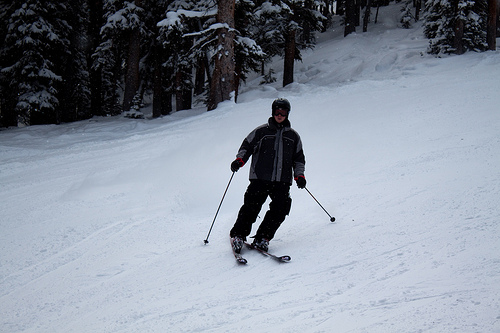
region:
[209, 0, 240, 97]
a large tree trunk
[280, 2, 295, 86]
a large tree trunk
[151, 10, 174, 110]
a large tree trunk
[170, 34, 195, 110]
a large tree trunk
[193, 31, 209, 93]
a large tree trunk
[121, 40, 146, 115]
a large tree trunk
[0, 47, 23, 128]
a large tree trunk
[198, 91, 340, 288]
a person skating on ice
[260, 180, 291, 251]
a person's leg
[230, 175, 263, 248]
a person's leg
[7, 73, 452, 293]
Snow is covering the ground.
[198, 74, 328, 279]
The person is wearing a snow suit.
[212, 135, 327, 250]
The person has poles in their hands.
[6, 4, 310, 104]
Pine trees in the background.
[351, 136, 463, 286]
The snow is white.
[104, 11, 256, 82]
Snow is covering the trees.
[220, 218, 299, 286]
Skis on the person's feet.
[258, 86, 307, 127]
Googles on the person's head.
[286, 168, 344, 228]
The poles are black.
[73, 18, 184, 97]
The leaves are green.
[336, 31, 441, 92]
a few piles of snow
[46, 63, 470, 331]
a snow covered slope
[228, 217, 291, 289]
a pair of skis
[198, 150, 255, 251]
a black ski pole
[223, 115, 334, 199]
a grey and blue jacket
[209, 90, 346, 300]
a young person skiing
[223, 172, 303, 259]
a pair of black snow pants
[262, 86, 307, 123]
a hard black helmet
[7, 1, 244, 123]
a few snow covered trees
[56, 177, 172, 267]
ski tracks in the snow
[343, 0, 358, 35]
a large tree trunk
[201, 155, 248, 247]
a skating stick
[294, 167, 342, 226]
a skating stick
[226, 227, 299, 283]
skating skis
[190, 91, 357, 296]
a person skating in ice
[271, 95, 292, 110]
a black hat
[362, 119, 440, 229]
a section of snow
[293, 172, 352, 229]
the left ski pole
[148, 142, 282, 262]
the right ski pole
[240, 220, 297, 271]
the left used ski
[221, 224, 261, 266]
the right used ski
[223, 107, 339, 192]
a used snow jacket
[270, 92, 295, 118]
a black ski helmet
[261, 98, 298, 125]
set of ski goggles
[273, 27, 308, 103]
a brown tree trunk